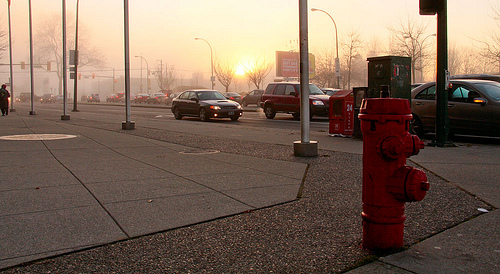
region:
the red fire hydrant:
[329, 71, 430, 260]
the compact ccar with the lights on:
[162, 82, 244, 134]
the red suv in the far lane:
[261, 78, 326, 120]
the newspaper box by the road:
[326, 86, 358, 156]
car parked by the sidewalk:
[428, 63, 499, 127]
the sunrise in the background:
[209, 48, 254, 94]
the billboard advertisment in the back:
[274, 43, 326, 83]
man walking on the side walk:
[2, 79, 14, 118]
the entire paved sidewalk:
[17, 89, 492, 251]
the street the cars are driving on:
[62, 93, 486, 174]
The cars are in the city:
[65, 5, 498, 262]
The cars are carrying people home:
[116, 15, 481, 256]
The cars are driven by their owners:
[115, 31, 496, 251]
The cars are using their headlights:
[136, 15, 497, 266]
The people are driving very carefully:
[130, 35, 491, 260]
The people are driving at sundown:
[116, 37, 477, 252]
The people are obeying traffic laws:
[136, 32, 496, 243]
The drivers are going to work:
[136, 6, 494, 256]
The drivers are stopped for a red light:
[116, 20, 496, 256]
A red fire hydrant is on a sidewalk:
[333, 87, 448, 261]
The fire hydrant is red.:
[349, 85, 439, 258]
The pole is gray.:
[285, 0, 326, 161]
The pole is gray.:
[114, 0, 144, 135]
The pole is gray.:
[53, 0, 75, 123]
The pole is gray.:
[23, 0, 41, 121]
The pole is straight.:
[3, 0, 20, 115]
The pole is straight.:
[24, 0, 40, 117]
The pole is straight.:
[57, 0, 77, 125]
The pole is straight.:
[112, 0, 142, 136]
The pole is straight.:
[288, 0, 322, 160]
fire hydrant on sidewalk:
[344, 80, 434, 258]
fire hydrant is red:
[348, 95, 433, 256]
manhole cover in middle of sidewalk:
[4, 128, 77, 147]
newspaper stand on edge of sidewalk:
[323, 83, 355, 141]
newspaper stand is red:
[328, 83, 350, 143]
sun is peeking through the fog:
[233, 58, 256, 80]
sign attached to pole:
[67, 48, 79, 69]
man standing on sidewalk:
[1, 83, 14, 121]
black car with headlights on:
[166, 85, 246, 130]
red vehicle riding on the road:
[256, 76, 333, 124]